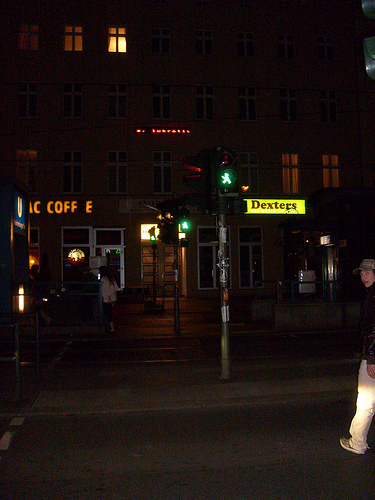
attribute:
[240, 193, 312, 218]
sign — yellow, bright, narrow, light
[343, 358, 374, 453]
pants — white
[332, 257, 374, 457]
man — looking, crossing, staring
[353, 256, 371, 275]
hat — white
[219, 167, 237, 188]
light — green, lit, bright, vibrant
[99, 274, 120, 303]
jacket — white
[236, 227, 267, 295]
window — white, closed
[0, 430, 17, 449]
line — white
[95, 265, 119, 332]
woman — walking, standing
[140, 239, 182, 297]
doorway — black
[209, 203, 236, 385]
pole — silver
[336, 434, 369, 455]
shoe — white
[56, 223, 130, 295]
window — white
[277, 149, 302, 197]
curtain — white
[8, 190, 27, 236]
sign — blue, white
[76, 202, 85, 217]
letter — out